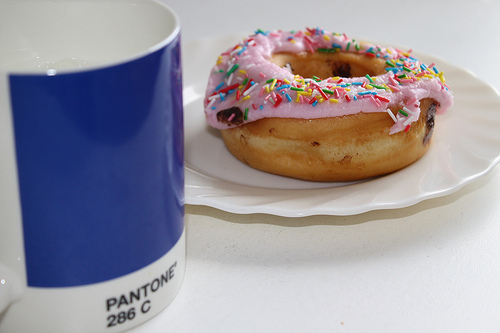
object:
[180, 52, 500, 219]
plate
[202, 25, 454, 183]
donut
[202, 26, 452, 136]
frosting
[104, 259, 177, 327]
writing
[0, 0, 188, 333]
mug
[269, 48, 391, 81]
hole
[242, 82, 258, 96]
sprinkle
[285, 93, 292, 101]
sprinkle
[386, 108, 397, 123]
sprinkle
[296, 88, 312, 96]
sprinkle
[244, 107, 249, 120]
sprinkle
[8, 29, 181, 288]
square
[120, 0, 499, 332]
table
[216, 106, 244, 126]
smear